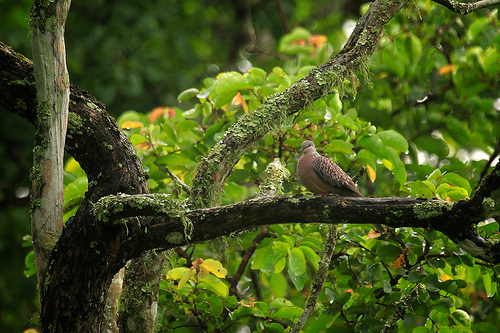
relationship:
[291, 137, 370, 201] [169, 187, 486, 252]
bird on branch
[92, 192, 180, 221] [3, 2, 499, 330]
nest growing on tree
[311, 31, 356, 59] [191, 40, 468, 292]
leaf on tree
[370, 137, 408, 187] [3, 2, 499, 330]
leaf on tree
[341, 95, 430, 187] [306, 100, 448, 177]
leaf on tree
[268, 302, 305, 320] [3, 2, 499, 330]
leaf on tree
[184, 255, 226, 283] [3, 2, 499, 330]
leaf on tree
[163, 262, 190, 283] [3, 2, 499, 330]
leaf on tree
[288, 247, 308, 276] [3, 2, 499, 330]
leaf on tree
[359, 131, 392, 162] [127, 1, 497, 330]
leaf on tree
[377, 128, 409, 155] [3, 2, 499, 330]
leaf on tree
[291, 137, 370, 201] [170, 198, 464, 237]
bird sitting on branch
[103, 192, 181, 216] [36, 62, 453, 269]
nest built in tree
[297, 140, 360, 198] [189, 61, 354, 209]
bird sitting under moss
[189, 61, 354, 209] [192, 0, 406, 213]
moss covered branch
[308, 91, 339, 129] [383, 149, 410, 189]
drop on leaf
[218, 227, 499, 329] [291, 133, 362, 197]
branches under bird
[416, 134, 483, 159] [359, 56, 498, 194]
gap between leaves